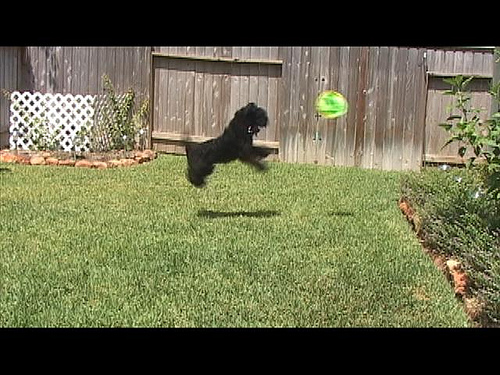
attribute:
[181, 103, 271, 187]
dog — jumping, black, playing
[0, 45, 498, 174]
fence — brown, wood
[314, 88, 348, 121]
ball — green, yellow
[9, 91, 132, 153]
trellis — white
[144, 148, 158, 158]
stone — brown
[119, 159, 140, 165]
stone — brown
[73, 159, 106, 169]
stone — brown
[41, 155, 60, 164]
stone — brown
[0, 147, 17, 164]
stone — brown